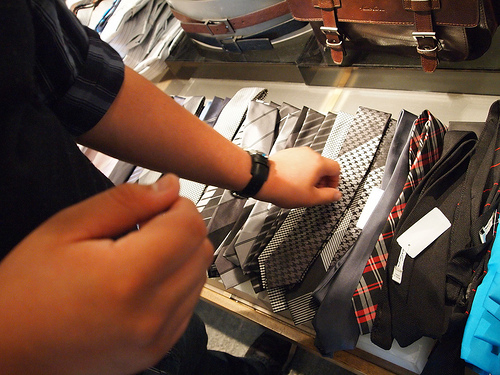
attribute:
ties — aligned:
[134, 69, 496, 359]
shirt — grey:
[2, 20, 122, 235]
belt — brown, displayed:
[176, 7, 295, 42]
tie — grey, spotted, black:
[271, 125, 394, 292]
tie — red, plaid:
[354, 112, 412, 344]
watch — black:
[235, 149, 270, 204]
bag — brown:
[291, 0, 498, 42]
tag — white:
[396, 196, 445, 285]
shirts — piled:
[140, 59, 465, 369]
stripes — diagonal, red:
[338, 116, 441, 321]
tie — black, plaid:
[379, 120, 479, 352]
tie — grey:
[380, 113, 416, 188]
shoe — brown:
[235, 338, 303, 371]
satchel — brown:
[284, 3, 497, 24]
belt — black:
[198, 43, 304, 70]